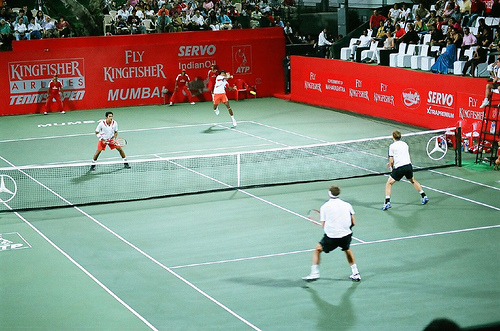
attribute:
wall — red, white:
[7, 28, 279, 110]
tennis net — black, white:
[56, 137, 336, 199]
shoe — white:
[303, 265, 324, 285]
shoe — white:
[340, 263, 363, 282]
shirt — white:
[93, 123, 120, 143]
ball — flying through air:
[251, 89, 259, 96]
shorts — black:
[321, 229, 356, 251]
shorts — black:
[391, 160, 416, 180]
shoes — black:
[298, 268, 362, 288]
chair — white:
[387, 39, 404, 66]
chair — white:
[399, 44, 411, 66]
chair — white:
[407, 44, 426, 67]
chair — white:
[422, 54, 431, 69]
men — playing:
[239, 119, 481, 306]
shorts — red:
[97, 137, 121, 150]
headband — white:
[304, 186, 349, 198]